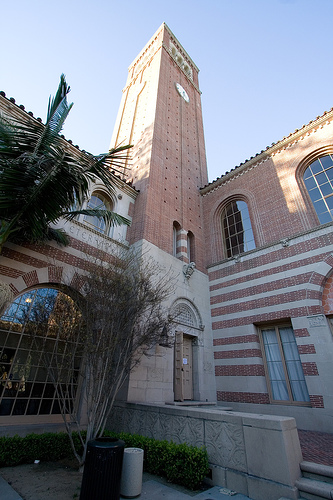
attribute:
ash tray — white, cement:
[121, 447, 144, 498]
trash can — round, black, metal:
[84, 437, 124, 499]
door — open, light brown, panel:
[173, 332, 183, 400]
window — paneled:
[255, 317, 311, 404]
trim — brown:
[257, 319, 314, 407]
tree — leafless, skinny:
[14, 235, 194, 469]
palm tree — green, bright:
[1, 74, 130, 254]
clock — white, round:
[176, 80, 189, 101]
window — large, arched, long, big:
[2, 285, 87, 417]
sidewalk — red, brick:
[298, 430, 332, 462]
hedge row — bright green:
[1, 430, 207, 488]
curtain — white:
[265, 328, 310, 401]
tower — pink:
[107, 22, 210, 274]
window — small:
[173, 222, 177, 257]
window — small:
[190, 235, 195, 262]